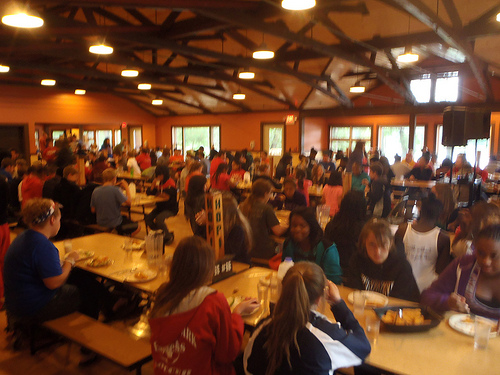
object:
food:
[390, 312, 421, 319]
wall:
[2, 90, 499, 162]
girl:
[143, 235, 246, 375]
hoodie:
[144, 282, 243, 375]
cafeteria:
[0, 0, 500, 375]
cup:
[474, 322, 493, 350]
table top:
[378, 324, 497, 374]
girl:
[0, 199, 88, 324]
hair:
[20, 197, 62, 229]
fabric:
[29, 199, 55, 223]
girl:
[420, 222, 500, 324]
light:
[252, 51, 274, 59]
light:
[278, 0, 316, 10]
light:
[398, 53, 418, 63]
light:
[350, 87, 366, 92]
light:
[2, 14, 44, 28]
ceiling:
[0, 1, 500, 117]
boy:
[145, 163, 180, 242]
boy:
[90, 166, 138, 234]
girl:
[239, 261, 368, 375]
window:
[171, 122, 220, 161]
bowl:
[372, 304, 444, 331]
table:
[46, 231, 498, 372]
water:
[145, 232, 163, 270]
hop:
[205, 194, 226, 258]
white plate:
[107, 266, 160, 283]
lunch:
[380, 308, 432, 327]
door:
[261, 123, 285, 167]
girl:
[280, 205, 342, 287]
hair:
[258, 260, 327, 375]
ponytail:
[261, 271, 312, 369]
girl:
[345, 218, 419, 300]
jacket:
[234, 295, 371, 375]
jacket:
[280, 237, 343, 285]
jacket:
[416, 252, 500, 317]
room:
[0, 0, 500, 375]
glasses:
[365, 241, 388, 250]